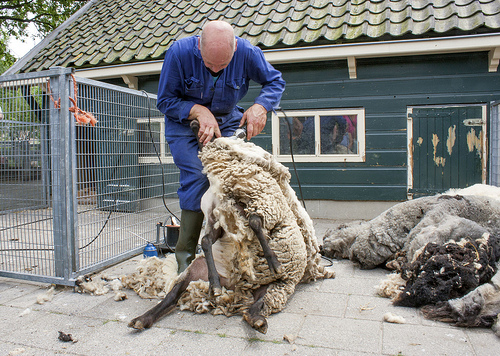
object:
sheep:
[127, 120, 336, 335]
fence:
[0, 66, 181, 285]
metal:
[49, 75, 79, 280]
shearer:
[213, 121, 260, 145]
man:
[156, 21, 285, 276]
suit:
[156, 35, 286, 210]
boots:
[175, 210, 205, 275]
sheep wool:
[318, 184, 500, 336]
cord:
[278, 107, 307, 211]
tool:
[240, 119, 247, 132]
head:
[188, 120, 265, 168]